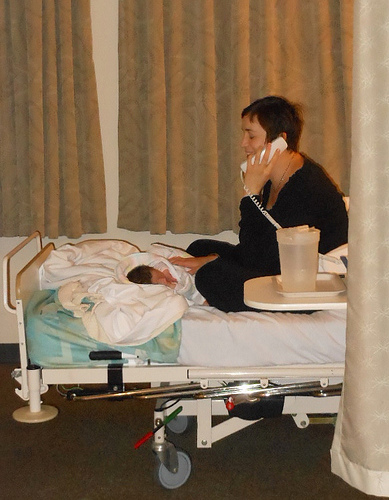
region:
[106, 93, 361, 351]
A woman and a baby in a hospital bed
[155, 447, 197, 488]
A small grey wheel on the bed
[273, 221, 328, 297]
A clear plastic cup on the table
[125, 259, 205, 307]
A newborn baby in the bed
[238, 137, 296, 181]
A white phone in the woman's hand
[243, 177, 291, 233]
A curling white cord on the phone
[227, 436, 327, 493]
Grey carpet beneath the bed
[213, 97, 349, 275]
The woman is talking on the phone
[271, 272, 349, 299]
A small white tray on the table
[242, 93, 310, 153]
The woman has short brown hair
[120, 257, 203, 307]
newborn baby on bed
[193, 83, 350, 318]
woman on the telephone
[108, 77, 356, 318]
woman on telephone with newborn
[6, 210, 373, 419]
hospital bed with baby and mom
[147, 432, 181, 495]
part of a wheel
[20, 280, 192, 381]
green sheets on hospital bed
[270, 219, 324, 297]
pitcher of water on table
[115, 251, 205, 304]
newborn with black hair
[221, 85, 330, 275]
woman wearing long necklace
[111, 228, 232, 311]
woman touching newborn baby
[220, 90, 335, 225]
A lady talking on the phone.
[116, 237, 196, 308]
The baby is in the bed.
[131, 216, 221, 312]
The lady is touching the baby.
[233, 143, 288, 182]
The lady has phone in her hand.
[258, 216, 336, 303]
Pitcher on the table.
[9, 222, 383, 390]
The lady sitting in a hospital bed.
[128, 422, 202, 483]
The bed has wheels.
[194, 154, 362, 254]
The lady is wearing black.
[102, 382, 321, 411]
Railing on the hospital bed.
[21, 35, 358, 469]
new mom and baby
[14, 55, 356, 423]
new mom and baby in hospital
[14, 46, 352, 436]
new mom and baby in hospital room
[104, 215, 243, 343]
new baby swattled up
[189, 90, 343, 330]
new mom wearing all black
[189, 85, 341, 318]
new mom talking on the phone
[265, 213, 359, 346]
a clear pitcher of water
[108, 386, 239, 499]
wheels on a hospital bed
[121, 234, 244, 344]
new baby with dark hair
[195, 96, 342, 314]
woman talking over the phone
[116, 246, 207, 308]
newborn baby laying on bed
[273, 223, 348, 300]
pitcher on tray next to bed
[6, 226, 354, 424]
baby and woman on hospital bed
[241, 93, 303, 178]
woman with short dark hair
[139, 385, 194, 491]
bed on wheels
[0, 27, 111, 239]
dark tan curtain is drawn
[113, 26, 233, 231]
dark tan curtain is drawn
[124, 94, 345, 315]
woman caressing baby while speaking on the phone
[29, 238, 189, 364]
white and turquoise bedding on bed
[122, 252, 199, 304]
The baby in the bed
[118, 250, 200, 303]
A baby in the bed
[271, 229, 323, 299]
The clear water pitcher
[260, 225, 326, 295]
A clear water pitcher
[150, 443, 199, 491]
The left bed wheel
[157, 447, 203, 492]
A left bed wheel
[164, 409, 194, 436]
A right bed wheel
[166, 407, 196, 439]
The right bed wheel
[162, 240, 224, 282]
A hand of the man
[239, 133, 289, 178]
phone in a person's hand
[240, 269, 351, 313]
hospital table tray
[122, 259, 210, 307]
baby on a bed